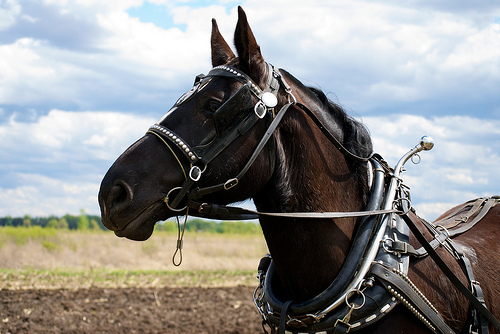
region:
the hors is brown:
[113, 51, 413, 330]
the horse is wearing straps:
[162, 42, 301, 222]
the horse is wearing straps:
[272, 86, 413, 298]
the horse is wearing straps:
[126, 80, 313, 287]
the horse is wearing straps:
[207, 132, 387, 328]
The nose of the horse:
[103, 172, 133, 210]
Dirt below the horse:
[1, 285, 271, 332]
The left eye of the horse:
[203, 98, 220, 115]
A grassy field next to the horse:
[6, 223, 267, 285]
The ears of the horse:
[208, 8, 266, 70]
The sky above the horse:
[2, 1, 499, 220]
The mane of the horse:
[299, 81, 368, 151]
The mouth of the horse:
[113, 195, 168, 237]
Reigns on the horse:
[161, 54, 486, 332]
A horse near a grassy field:
[99, 3, 499, 328]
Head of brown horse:
[98, 0, 278, 242]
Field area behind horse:
[31, 255, 125, 296]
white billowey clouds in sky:
[46, 123, 111, 150]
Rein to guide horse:
[211, 204, 384, 223]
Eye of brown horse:
[198, 93, 236, 113]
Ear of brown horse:
[230, 5, 268, 59]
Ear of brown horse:
[205, 18, 230, 56]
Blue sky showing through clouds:
[443, 90, 494, 116]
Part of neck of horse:
[301, 140, 336, 189]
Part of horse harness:
[147, 120, 238, 190]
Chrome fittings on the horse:
[397, 132, 440, 164]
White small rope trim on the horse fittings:
[347, 298, 391, 326]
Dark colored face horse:
[92, 69, 268, 248]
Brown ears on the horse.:
[206, 4, 264, 67]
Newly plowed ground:
[4, 288, 244, 332]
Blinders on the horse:
[208, 83, 266, 132]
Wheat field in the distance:
[4, 239, 260, 264]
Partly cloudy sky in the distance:
[305, 16, 498, 113]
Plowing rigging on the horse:
[360, 136, 498, 285]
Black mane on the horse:
[331, 88, 373, 156]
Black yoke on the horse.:
[256, 72, 432, 332]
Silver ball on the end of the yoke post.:
[415, 130, 430, 150]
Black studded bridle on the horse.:
[130, 46, 285, 206]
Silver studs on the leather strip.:
[147, 121, 194, 157]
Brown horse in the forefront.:
[86, 5, 491, 326]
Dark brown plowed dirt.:
[0, 285, 266, 330]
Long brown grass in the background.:
[2, 235, 268, 270]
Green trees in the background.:
[2, 211, 264, 234]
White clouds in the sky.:
[127, 4, 222, 76]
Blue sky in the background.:
[372, 89, 495, 121]